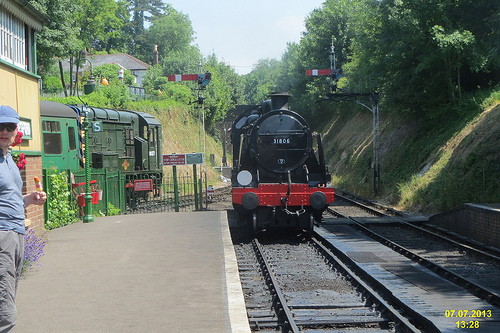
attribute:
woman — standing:
[1, 104, 26, 333]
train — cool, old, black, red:
[223, 91, 335, 245]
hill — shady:
[315, 72, 499, 220]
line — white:
[220, 209, 254, 333]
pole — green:
[76, 115, 95, 224]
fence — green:
[45, 167, 212, 216]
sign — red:
[132, 176, 158, 192]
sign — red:
[156, 151, 193, 169]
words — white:
[161, 155, 187, 167]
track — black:
[249, 214, 440, 333]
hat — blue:
[0, 101, 20, 131]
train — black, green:
[37, 100, 166, 204]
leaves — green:
[34, 3, 129, 60]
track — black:
[329, 195, 499, 314]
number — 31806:
[271, 137, 300, 146]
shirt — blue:
[2, 154, 25, 235]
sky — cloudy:
[131, 1, 341, 75]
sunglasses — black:
[0, 121, 19, 137]